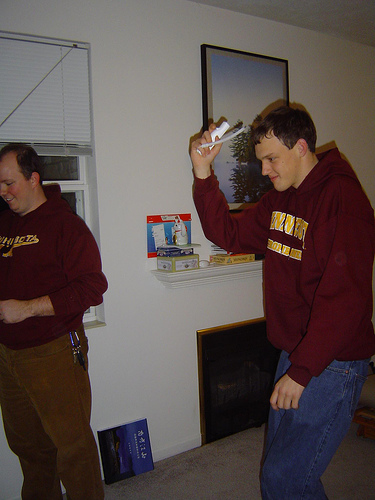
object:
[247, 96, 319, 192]
head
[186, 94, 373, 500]
person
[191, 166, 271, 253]
arm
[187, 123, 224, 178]
hand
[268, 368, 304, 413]
hand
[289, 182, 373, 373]
arm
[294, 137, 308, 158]
ear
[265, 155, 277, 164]
eye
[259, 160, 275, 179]
nose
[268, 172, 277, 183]
mouth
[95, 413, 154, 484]
book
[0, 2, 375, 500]
wall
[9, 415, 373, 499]
carpet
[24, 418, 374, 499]
floor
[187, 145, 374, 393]
sweater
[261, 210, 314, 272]
logo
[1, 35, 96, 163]
blinds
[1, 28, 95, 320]
window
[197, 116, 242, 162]
remote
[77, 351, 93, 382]
keys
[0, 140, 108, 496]
man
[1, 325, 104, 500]
pants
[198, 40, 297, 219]
picture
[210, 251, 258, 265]
book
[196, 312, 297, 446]
fireplace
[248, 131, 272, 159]
forehead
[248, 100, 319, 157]
hair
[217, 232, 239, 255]
elbow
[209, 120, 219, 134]
finger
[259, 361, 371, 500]
leg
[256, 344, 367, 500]
jeans